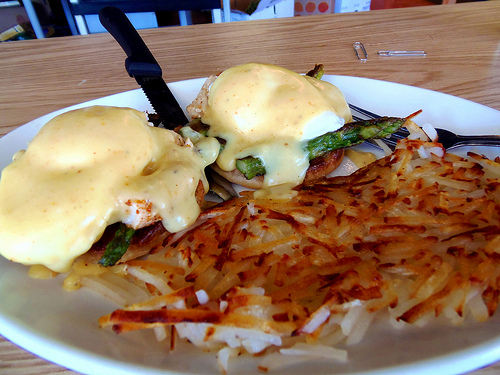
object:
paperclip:
[351, 39, 371, 59]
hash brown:
[275, 337, 353, 367]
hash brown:
[340, 294, 369, 342]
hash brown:
[219, 324, 285, 356]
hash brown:
[217, 340, 240, 372]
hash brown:
[83, 271, 137, 309]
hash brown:
[465, 289, 490, 323]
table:
[0, 0, 500, 375]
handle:
[97, 1, 161, 74]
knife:
[97, 4, 187, 130]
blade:
[134, 70, 190, 128]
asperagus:
[236, 116, 402, 180]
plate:
[0, 72, 500, 375]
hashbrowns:
[73, 123, 497, 374]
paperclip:
[377, 49, 427, 60]